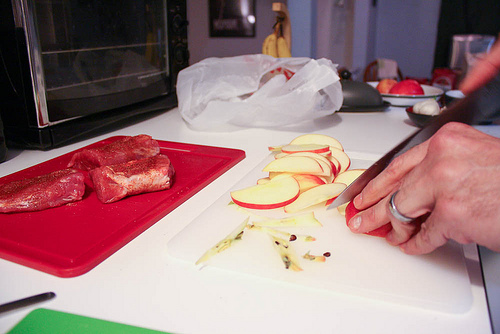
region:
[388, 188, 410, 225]
a ring is on the hand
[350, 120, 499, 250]
the person is holding an apple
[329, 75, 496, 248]
the person is slicing an apple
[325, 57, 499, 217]
the person is holding a knife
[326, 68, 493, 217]
the knife is made of metal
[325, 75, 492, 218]
the knife is made of steel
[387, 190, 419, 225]
the ring is made of metal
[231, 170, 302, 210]
a slice of apple that has been cut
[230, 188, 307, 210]
the apple skin is red in color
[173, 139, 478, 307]
the cutting board is white in color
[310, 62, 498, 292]
man is slicing the apples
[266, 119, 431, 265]
man is slicing the apples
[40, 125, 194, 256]
meat on the red tray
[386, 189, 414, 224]
men's plain silver wedding ring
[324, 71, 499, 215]
large, sharp kitchen knife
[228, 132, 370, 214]
pile of sliced apple pieces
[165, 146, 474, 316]
clear plastic cutting board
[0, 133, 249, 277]
red plastic cutting board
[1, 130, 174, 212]
three cuts of meat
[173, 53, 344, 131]
white plastic bag with red writing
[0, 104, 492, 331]
white counter top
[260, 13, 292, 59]
bunch of bananas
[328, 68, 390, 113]
grey pot lid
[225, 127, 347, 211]
Sliced apples on the cutting board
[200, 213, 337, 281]
The apple seeds on the cutting board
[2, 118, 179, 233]
The meat on the cutting board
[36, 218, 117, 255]
The cutting board is red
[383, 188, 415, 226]
The person is wearing a ring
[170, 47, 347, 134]
The plastic bag on the counter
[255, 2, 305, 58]
The bananas on the counter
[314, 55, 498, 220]
The person is holding the knife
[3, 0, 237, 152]
The toaster oven is the color black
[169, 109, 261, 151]
The counter is the color white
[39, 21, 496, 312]
picture taken indoors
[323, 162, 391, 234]
a person is cutting an apple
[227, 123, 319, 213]
the apple is in slices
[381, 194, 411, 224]
the person wears a ring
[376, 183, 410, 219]
the ring is on the left hand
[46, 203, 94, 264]
A red cutting board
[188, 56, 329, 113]
a plastic bag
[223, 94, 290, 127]
the bag is white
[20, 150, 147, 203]
three pieces of meat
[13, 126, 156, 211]
the meat is red